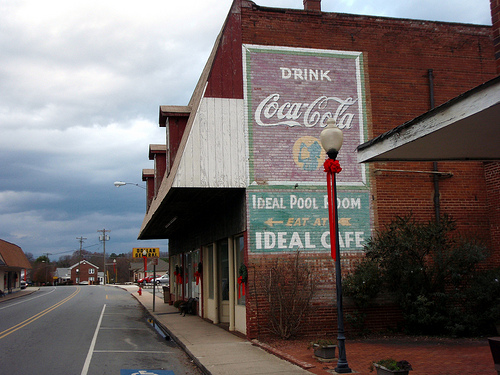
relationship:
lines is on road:
[0, 283, 83, 343] [1, 282, 211, 373]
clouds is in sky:
[1, 5, 227, 179] [2, 2, 493, 262]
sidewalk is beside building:
[119, 277, 300, 374] [138, 1, 498, 343]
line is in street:
[69, 300, 111, 375] [6, 286, 178, 374]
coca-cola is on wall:
[252, 89, 356, 131] [239, 17, 394, 283]